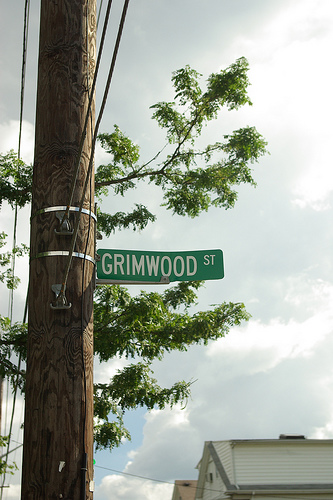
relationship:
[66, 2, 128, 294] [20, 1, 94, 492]
cables on pole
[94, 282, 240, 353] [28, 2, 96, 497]
limb behind post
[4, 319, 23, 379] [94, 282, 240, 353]
limb behind limb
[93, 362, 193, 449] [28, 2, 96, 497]
limb behind post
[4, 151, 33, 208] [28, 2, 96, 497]
limb behind post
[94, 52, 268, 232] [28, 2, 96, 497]
limb behind post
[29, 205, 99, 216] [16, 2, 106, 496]
silver band on pole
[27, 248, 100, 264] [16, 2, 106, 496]
silver band on pole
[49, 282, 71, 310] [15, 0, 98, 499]
latch on pole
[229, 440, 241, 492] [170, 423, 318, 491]
gutter on house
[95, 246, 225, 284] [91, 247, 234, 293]
sign on sign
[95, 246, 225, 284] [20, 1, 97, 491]
sign attached to pole